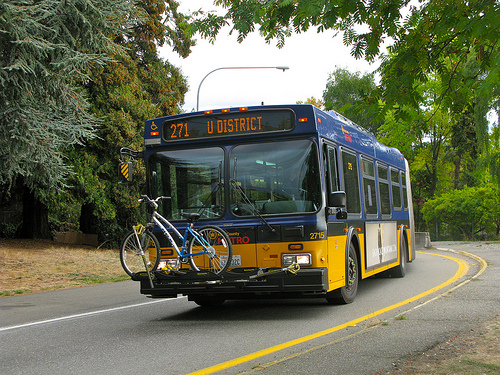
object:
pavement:
[111, 342, 160, 358]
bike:
[120, 194, 234, 277]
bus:
[118, 102, 416, 305]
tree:
[73, 160, 124, 249]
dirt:
[23, 258, 68, 276]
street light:
[195, 66, 289, 111]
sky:
[305, 41, 324, 51]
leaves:
[131, 53, 175, 74]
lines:
[185, 331, 326, 375]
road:
[68, 337, 146, 360]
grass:
[95, 275, 114, 283]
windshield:
[148, 138, 324, 224]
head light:
[281, 252, 312, 267]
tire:
[326, 241, 359, 305]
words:
[228, 119, 235, 132]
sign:
[208, 116, 263, 133]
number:
[170, 123, 190, 139]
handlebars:
[141, 194, 148, 197]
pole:
[164, 66, 276, 112]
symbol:
[309, 231, 325, 239]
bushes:
[419, 182, 500, 241]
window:
[363, 178, 378, 220]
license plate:
[219, 255, 242, 268]